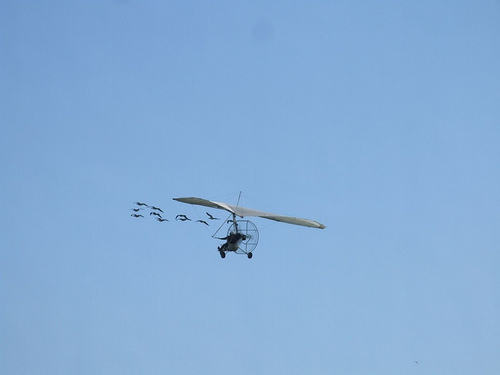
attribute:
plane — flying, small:
[174, 190, 327, 258]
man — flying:
[214, 231, 236, 251]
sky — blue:
[0, 1, 500, 374]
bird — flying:
[132, 201, 149, 207]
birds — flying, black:
[130, 199, 234, 224]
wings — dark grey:
[132, 200, 149, 208]